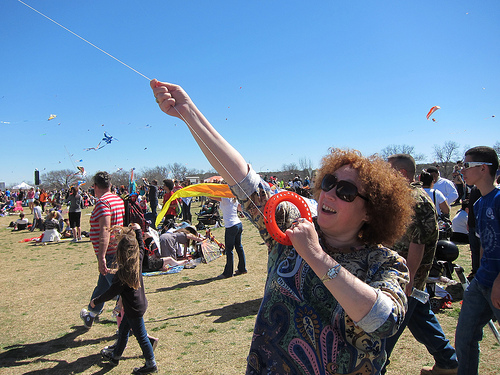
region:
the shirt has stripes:
[83, 197, 135, 277]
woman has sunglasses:
[161, 140, 404, 373]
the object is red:
[253, 188, 330, 263]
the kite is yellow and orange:
[167, 173, 248, 228]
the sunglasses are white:
[457, 154, 490, 177]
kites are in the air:
[34, 98, 160, 159]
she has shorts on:
[57, 194, 89, 244]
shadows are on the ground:
[18, 325, 98, 374]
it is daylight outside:
[20, 139, 497, 370]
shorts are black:
[66, 208, 83, 233]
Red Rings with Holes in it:
[261, 190, 315, 245]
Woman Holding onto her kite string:
[148, 75, 408, 373]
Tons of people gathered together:
[1, 151, 498, 372]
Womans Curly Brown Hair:
[312, 148, 414, 252]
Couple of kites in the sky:
[33, 103, 164, 178]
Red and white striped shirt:
[88, 193, 127, 254]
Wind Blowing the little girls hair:
[89, 226, 163, 371]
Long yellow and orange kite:
[150, 178, 229, 234]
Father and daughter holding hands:
[81, 172, 158, 372]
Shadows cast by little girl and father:
[0, 311, 120, 373]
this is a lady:
[259, 163, 418, 373]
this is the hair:
[366, 168, 415, 236]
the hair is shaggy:
[367, 174, 412, 227]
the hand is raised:
[140, 79, 227, 163]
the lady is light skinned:
[221, 150, 237, 165]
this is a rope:
[99, 42, 155, 96]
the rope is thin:
[113, 53, 133, 81]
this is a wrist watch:
[318, 263, 343, 283]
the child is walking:
[104, 235, 154, 367]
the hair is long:
[120, 250, 142, 288]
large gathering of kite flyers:
[3, 144, 498, 371]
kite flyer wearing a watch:
[320, 260, 341, 283]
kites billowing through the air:
[0, 107, 156, 185]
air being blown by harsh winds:
[106, 222, 141, 290]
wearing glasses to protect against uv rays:
[320, 157, 495, 202]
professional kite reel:
[261, 190, 308, 245]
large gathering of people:
[0, 145, 495, 371]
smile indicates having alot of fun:
[317, 147, 408, 247]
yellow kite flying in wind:
[154, 180, 236, 227]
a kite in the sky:
[387, 93, 462, 152]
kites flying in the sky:
[0, 77, 163, 175]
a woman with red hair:
[319, 149, 436, 234]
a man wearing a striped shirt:
[88, 162, 122, 244]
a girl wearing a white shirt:
[221, 190, 243, 232]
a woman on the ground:
[144, 217, 216, 278]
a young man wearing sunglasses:
[458, 142, 493, 200]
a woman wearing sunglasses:
[296, 148, 389, 233]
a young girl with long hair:
[115, 223, 145, 310]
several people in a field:
[1, 154, 300, 276]